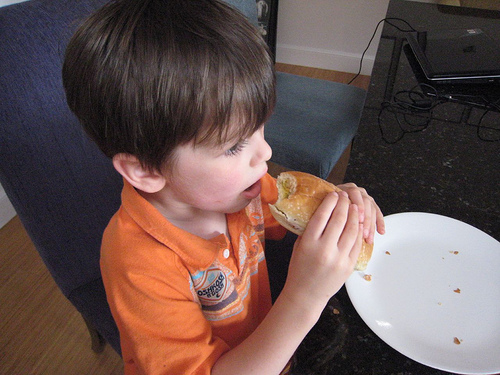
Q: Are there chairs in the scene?
A: Yes, there is a chair.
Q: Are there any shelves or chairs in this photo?
A: Yes, there is a chair.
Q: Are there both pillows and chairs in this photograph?
A: No, there is a chair but no pillows.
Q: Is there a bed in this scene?
A: No, there are no beds.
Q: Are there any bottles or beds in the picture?
A: No, there are no beds or bottles.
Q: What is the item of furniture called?
A: The piece of furniture is a chair.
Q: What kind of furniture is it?
A: The piece of furniture is a chair.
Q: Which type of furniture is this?
A: This is a chair.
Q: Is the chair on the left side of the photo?
A: Yes, the chair is on the left of the image.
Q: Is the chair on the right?
A: No, the chair is on the left of the image.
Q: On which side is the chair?
A: The chair is on the left of the image.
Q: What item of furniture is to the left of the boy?
A: The piece of furniture is a chair.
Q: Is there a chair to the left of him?
A: Yes, there is a chair to the left of the boy.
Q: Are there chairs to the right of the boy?
A: No, the chair is to the left of the boy.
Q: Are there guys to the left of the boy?
A: No, there is a chair to the left of the boy.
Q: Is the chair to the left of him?
A: Yes, the chair is to the left of a boy.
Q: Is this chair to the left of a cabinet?
A: No, the chair is to the left of a boy.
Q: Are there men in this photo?
A: No, there are no men.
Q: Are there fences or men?
A: No, there are no men or fences.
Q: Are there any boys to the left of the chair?
A: No, the boy is to the right of the chair.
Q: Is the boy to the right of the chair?
A: Yes, the boy is to the right of the chair.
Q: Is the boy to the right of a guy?
A: No, the boy is to the right of the chair.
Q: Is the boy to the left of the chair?
A: No, the boy is to the right of the chair.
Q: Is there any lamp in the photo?
A: No, there are no lamps.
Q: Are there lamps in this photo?
A: No, there are no lamps.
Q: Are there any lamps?
A: No, there are no lamps.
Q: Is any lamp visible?
A: No, there are no lamps.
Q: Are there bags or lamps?
A: No, there are no lamps or bags.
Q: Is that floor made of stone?
A: No, the floor is made of hardwood.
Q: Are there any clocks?
A: No, there are no clocks.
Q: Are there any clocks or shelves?
A: No, there are no clocks or shelves.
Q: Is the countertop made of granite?
A: Yes, the countertop is made of granite.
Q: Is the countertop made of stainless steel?
A: No, the countertop is made of granite.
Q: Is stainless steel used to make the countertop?
A: No, the countertop is made of granite.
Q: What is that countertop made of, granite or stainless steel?
A: The countertop is made of granite.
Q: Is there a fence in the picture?
A: No, there are no fences.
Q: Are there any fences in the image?
A: No, there are no fences.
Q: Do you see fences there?
A: No, there are no fences.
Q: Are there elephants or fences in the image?
A: No, there are no fences or elephants.